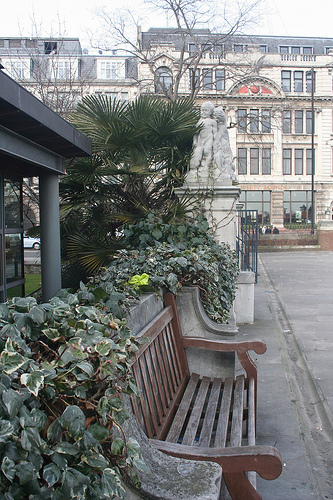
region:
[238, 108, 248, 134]
window on tall beige building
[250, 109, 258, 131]
window on tall beige building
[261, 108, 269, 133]
window on tall beige building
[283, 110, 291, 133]
window on tall beige building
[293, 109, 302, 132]
window on tall beige building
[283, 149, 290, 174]
window on tall beige building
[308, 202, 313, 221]
glass window on building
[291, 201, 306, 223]
glass window on building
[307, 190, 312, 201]
glass window on building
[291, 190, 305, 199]
glass window on building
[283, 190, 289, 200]
glass window on building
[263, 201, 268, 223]
glass window on building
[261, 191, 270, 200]
glass window on building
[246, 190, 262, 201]
glass window on building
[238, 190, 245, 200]
glass window on building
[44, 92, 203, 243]
palm plant by bench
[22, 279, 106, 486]
large section of green ivy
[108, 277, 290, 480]
dark brown wooden bench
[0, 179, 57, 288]
window of building behind bench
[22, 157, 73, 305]
concrete pillar by building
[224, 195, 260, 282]
metal fencing past bench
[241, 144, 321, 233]
beige building with windows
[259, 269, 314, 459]
grey concrete sidewalk by bench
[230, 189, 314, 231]
bottom set of windows of beige building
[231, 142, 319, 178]
top set of windows of beige building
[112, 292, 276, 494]
A worn brown bench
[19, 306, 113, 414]
A plant with ragged leaves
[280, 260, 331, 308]
A patch of gray street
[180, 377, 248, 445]
A bench seat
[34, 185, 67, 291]
A gray metal street pole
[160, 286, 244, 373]
A gray concrete planter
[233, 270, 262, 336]
A white cement wall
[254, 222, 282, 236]
Distant people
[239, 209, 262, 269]
A black wrought iron gate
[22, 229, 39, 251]
A portion of a white car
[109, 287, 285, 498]
a wooden bench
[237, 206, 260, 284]
a raw iron gate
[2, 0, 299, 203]
the bare leaves tree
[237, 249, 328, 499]
a grey sidewalk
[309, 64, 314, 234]
the narrow black pole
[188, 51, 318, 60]
words at the top of building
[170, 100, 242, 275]
a statue standing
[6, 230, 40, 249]
a car on the street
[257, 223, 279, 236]
people standind around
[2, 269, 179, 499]
the bushes behind the bench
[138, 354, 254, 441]
a bench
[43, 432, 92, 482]
the leaves are green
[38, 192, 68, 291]
a grey pole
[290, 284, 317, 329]
the ground